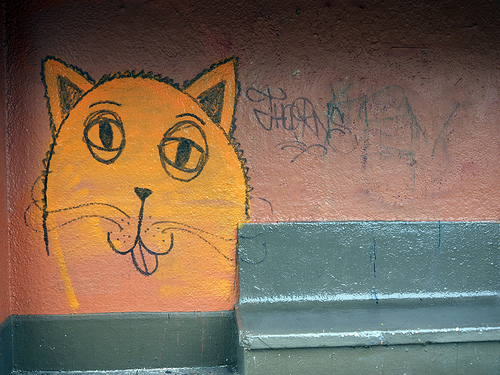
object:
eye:
[82, 110, 124, 164]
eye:
[158, 121, 209, 182]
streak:
[370, 238, 379, 305]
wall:
[0, 19, 499, 313]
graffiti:
[26, 55, 460, 309]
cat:
[25, 54, 253, 310]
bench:
[233, 220, 498, 373]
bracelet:
[245, 79, 427, 161]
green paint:
[0, 220, 499, 374]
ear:
[41, 55, 93, 130]